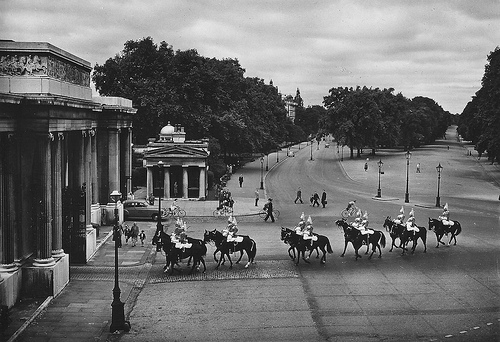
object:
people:
[310, 189, 328, 209]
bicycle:
[164, 207, 187, 218]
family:
[112, 221, 146, 247]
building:
[1, 38, 134, 308]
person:
[294, 186, 303, 203]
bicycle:
[341, 207, 362, 218]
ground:
[369, 83, 394, 129]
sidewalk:
[14, 218, 165, 341]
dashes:
[440, 323, 492, 338]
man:
[442, 200, 452, 222]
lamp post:
[107, 190, 128, 333]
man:
[170, 215, 189, 245]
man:
[302, 215, 317, 241]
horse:
[280, 226, 333, 266]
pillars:
[16, 128, 98, 255]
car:
[123, 199, 167, 221]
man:
[406, 207, 420, 238]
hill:
[107, 119, 497, 212]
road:
[266, 136, 392, 205]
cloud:
[0, 0, 500, 77]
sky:
[2, 2, 499, 112]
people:
[287, 201, 454, 238]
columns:
[4, 127, 134, 272]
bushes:
[314, 87, 455, 157]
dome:
[159, 119, 174, 140]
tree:
[93, 36, 500, 187]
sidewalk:
[129, 140, 318, 341]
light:
[155, 160, 164, 228]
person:
[263, 198, 276, 223]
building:
[134, 122, 211, 202]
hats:
[400, 206, 405, 214]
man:
[223, 216, 238, 247]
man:
[302, 215, 313, 237]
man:
[356, 210, 375, 235]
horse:
[428, 216, 462, 248]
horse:
[383, 216, 427, 255]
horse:
[335, 218, 386, 262]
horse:
[204, 228, 257, 270]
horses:
[152, 229, 207, 276]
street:
[16, 134, 498, 340]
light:
[375, 158, 384, 198]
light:
[404, 150, 412, 203]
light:
[432, 161, 443, 208]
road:
[340, 268, 430, 324]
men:
[294, 212, 305, 235]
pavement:
[151, 284, 314, 340]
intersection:
[171, 204, 284, 243]